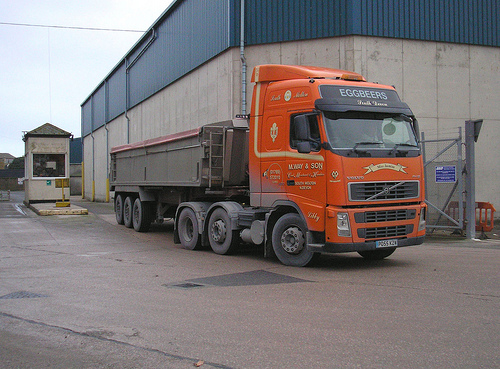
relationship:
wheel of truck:
[266, 211, 318, 270] [103, 58, 436, 270]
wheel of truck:
[359, 235, 397, 264] [103, 58, 436, 270]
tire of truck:
[111, 195, 128, 226] [103, 58, 436, 270]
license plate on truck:
[375, 237, 397, 250] [103, 58, 436, 270]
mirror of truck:
[289, 111, 317, 149] [103, 58, 436, 270]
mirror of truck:
[294, 138, 312, 158] [103, 58, 436, 270]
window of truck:
[287, 112, 320, 157] [103, 58, 436, 270]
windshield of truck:
[318, 105, 421, 157] [103, 58, 436, 270]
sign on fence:
[431, 162, 457, 188] [415, 127, 467, 245]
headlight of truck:
[333, 208, 353, 243] [103, 58, 436, 270]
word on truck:
[335, 83, 390, 103] [103, 58, 436, 270]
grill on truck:
[343, 176, 422, 211] [103, 58, 436, 270]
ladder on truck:
[205, 126, 231, 190] [103, 58, 436, 270]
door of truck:
[283, 107, 326, 237] [103, 58, 436, 270]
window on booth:
[27, 152, 69, 179] [18, 118, 74, 207]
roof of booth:
[21, 121, 74, 143] [18, 118, 74, 207]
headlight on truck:
[333, 208, 353, 243] [103, 58, 436, 270]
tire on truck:
[111, 195, 128, 226] [103, 58, 436, 270]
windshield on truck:
[318, 105, 421, 157] [103, 58, 436, 270]